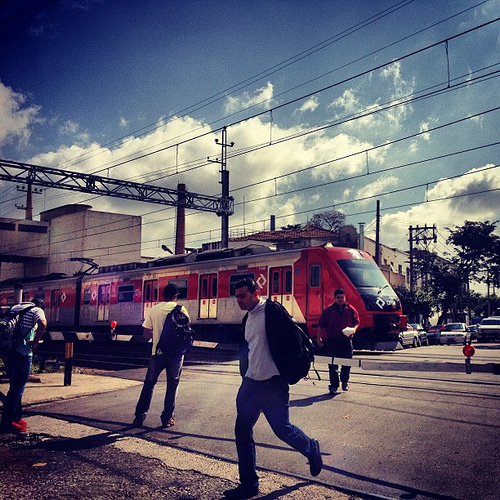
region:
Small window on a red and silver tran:
[305, 261, 321, 290]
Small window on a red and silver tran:
[268, 263, 290, 296]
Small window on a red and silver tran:
[193, 273, 220, 293]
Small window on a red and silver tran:
[162, 274, 188, 299]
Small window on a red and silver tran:
[142, 280, 161, 300]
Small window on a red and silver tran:
[112, 281, 132, 306]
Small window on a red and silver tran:
[95, 283, 110, 305]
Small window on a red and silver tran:
[76, 284, 97, 309]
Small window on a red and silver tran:
[46, 287, 64, 311]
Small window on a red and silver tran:
[332, 254, 387, 291]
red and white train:
[0, 243, 407, 349]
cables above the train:
[1, 24, 493, 273]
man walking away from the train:
[222, 271, 320, 498]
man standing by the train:
[317, 286, 363, 391]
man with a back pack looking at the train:
[128, 273, 198, 438]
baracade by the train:
[0, 328, 497, 387]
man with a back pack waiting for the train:
[0, 287, 55, 437]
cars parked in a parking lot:
[388, 318, 498, 345]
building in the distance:
[1, 198, 141, 279]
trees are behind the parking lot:
[402, 217, 497, 315]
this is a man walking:
[218, 277, 321, 499]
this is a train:
[0, 241, 402, 348]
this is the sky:
[0, 0, 499, 294]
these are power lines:
[1, 0, 496, 270]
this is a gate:
[40, 320, 496, 377]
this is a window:
[334, 257, 396, 302]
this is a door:
[194, 273, 224, 322]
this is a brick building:
[196, 223, 470, 328]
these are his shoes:
[220, 435, 325, 498]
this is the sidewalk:
[21, 384, 496, 498]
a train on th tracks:
[159, 189, 472, 418]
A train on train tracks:
[144, 196, 494, 407]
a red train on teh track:
[224, 211, 475, 343]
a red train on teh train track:
[285, 218, 497, 453]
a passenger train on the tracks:
[222, 220, 497, 422]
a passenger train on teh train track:
[207, 220, 490, 445]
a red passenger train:
[137, 184, 489, 479]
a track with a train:
[194, 210, 499, 395]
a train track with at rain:
[239, 231, 453, 434]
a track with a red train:
[197, 222, 496, 417]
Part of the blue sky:
[111, 47, 173, 74]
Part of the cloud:
[1, 103, 9, 127]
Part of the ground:
[341, 419, 384, 453]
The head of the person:
[231, 276, 261, 311]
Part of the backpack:
[173, 325, 185, 348]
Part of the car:
[444, 336, 459, 341]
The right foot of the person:
[221, 478, 264, 498]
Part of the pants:
[242, 394, 251, 426]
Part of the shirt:
[248, 318, 261, 354]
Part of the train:
[296, 262, 330, 282]